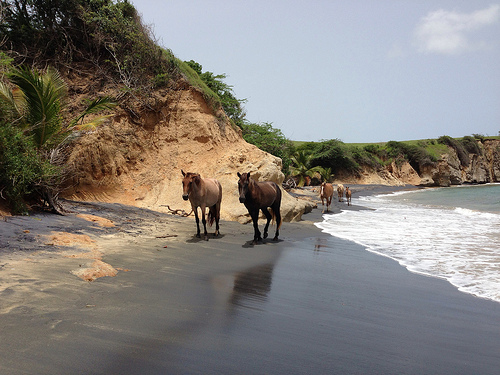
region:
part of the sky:
[231, 0, 282, 72]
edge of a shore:
[317, 290, 373, 331]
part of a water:
[385, 189, 438, 260]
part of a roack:
[123, 169, 155, 206]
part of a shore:
[274, 304, 312, 359]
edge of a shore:
[356, 224, 418, 304]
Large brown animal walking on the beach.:
[166, 163, 236, 259]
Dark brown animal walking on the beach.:
[229, 163, 291, 253]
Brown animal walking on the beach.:
[313, 174, 337, 210]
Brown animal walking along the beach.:
[342, 184, 370, 221]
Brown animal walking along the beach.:
[333, 176, 347, 211]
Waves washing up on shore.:
[357, 173, 439, 338]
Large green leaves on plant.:
[21, 75, 74, 157]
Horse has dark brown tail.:
[271, 189, 290, 236]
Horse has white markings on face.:
[320, 183, 327, 196]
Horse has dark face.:
[236, 190, 248, 203]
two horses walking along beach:
[169, 150, 293, 256]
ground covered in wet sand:
[181, 270, 386, 368]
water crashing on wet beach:
[309, 225, 454, 315]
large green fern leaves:
[0, 62, 118, 204]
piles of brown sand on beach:
[50, 203, 127, 288]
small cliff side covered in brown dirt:
[166, 110, 243, 167]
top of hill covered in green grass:
[293, 132, 438, 164]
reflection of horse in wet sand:
[198, 248, 292, 322]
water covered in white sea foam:
[381, 208, 466, 259]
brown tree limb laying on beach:
[158, 200, 192, 222]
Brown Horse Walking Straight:
[181, 168, 222, 239]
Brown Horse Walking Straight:
[238, 171, 283, 245]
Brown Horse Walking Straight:
[320, 183, 332, 209]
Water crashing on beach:
[319, 181, 499, 306]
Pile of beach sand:
[66, 73, 313, 218]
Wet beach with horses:
[0, 170, 499, 372]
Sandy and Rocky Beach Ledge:
[283, 140, 499, 184]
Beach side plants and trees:
[2, 52, 97, 203]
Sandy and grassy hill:
[5, 0, 310, 220]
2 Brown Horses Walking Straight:
[336, 183, 354, 204]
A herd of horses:
[171, 138, 363, 251]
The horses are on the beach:
[162, 137, 364, 253]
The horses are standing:
[172, 147, 360, 255]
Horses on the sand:
[173, 161, 297, 256]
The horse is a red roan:
[174, 159, 239, 253]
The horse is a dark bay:
[225, 161, 301, 256]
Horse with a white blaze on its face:
[308, 174, 342, 219]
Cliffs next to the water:
[300, 118, 480, 205]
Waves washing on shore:
[281, 183, 492, 340]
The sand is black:
[156, 253, 365, 352]